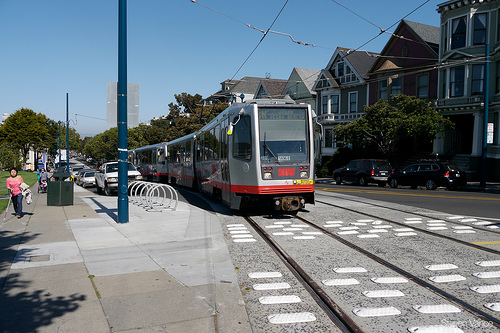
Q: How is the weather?
A: Bright.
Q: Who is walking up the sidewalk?
A: A woman.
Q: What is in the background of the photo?
A: Trees.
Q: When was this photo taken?
A: Daytime.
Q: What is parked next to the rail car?
A: Automobiles.